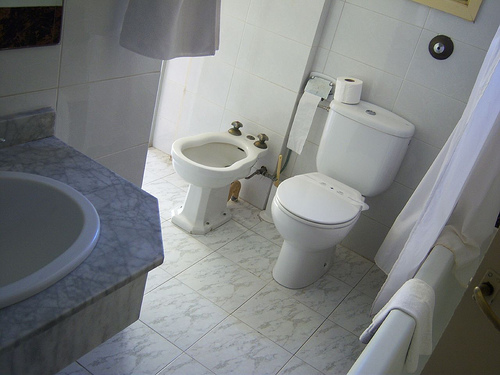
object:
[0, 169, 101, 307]
sink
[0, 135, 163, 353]
counter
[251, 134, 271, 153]
brass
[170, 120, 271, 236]
toilet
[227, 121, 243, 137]
knob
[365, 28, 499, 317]
curtain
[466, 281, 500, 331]
handle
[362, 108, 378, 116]
flush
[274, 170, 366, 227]
bowl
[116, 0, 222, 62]
towel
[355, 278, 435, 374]
mat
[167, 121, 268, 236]
bidet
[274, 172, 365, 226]
lid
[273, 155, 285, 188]
toilet brush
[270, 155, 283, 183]
handle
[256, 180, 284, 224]
container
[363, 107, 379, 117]
button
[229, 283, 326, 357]
tile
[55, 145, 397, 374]
floor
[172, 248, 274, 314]
tile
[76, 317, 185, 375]
tile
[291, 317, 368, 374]
tile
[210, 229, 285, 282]
tile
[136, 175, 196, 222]
tile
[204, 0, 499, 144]
bathroom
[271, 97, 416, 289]
toilet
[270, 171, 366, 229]
seat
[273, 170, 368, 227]
seal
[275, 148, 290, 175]
pipe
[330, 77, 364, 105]
paper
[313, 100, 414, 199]
tank